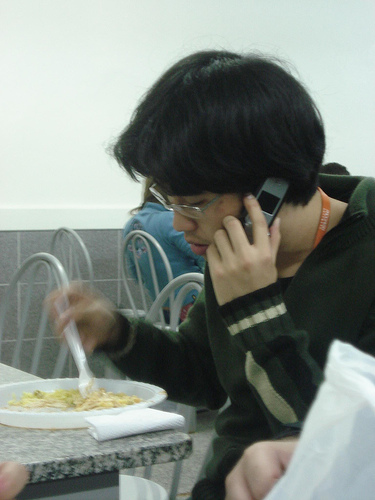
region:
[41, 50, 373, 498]
young man eating some noodles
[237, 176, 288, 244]
cell phone in man's hand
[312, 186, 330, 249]
orange band around man's neck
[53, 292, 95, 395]
white fork in the man's hand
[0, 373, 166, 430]
a white bowl of noodles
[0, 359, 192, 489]
a granite table top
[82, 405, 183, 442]
a napkin on the table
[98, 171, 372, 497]
a sweatshirt on the man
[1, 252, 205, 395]
a couple of chairs at the table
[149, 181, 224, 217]
glasses on the man's face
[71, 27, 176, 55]
two tone blue color on wall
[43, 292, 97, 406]
large silver spoon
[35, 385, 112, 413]
thin white noodles on plate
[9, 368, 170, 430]
large white shiny paper plate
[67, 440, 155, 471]
black and white stone counter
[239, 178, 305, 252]
black and silver phone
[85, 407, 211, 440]
white folded napkin on table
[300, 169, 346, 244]
orange lanyard around man's neck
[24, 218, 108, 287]
top of gray round chair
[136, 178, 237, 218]
clear glasses on man's face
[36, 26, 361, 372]
Young man talking on phone.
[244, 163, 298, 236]
A grey cell phone.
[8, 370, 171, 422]
A round white plate.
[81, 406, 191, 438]
A white folded napkin.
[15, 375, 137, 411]
Food on a plate.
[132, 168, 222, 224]
A pair of silver glasses.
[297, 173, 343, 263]
An orange cord around boy's neck.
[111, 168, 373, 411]
Young man wearing sweater.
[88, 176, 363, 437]
A long sleeve sweater.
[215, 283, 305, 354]
White stripe around sweater cuff.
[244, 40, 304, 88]
loose hair on man's head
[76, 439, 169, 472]
edge of stone table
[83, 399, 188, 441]
white napkin neatly folded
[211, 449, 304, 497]
person's finger in frame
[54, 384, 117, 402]
white pasta on plate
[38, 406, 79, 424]
edge of white plate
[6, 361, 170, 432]
large round white plate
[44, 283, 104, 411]
long silver fork on plate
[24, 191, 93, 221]
wide edge of white wall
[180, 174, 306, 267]
man talking on phone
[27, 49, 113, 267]
Wall is white and grey.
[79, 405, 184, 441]
Tissue is white color.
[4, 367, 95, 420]
Plate is white color.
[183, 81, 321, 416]
Man is holding cell phone in left hand.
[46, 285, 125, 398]
Man is holding fork in reght hand.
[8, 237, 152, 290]
Chair is grey color.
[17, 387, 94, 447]
Plate is in table.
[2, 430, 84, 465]
Table is grey color.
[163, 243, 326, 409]
Man is wearing green shirt.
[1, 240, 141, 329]
Tiles are fixed to the wall.